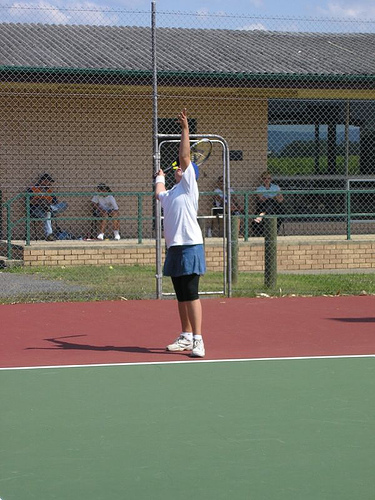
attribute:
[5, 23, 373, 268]
building — large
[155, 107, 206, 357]
player — tennis player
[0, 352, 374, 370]
line — white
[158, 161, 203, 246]
t-shirt — white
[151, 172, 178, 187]
wristband — white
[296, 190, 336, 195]
green — long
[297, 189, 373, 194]
pole — green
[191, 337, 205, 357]
shoe — white 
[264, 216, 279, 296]
green pole — tall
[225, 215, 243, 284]
green pole — tall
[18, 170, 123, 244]
people — sitting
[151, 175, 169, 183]
wrist — woman's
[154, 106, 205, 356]
tennis player — serving